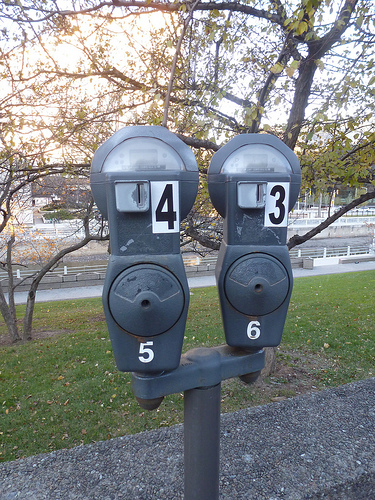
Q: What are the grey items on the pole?
A: Parking meters.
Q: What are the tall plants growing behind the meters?
A: Trees.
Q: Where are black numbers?
A: On the parking meter.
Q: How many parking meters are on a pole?
A: Two.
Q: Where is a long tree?
A: Behind the parking meter.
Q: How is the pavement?
A: Paved.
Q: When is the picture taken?
A: Daytime.